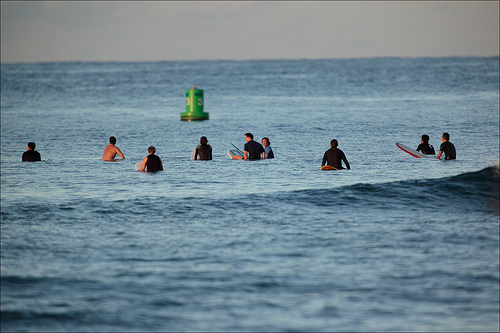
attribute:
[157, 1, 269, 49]
sky — gray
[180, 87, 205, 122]
buoy — floating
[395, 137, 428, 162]
white surfboard —  white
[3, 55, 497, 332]
ocean — blue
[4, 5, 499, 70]
sky —  gray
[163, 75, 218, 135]
buoy —  green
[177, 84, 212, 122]
buoy — green, yellow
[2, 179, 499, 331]
water — blue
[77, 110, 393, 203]
surfers — grouped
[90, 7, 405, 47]
sky — overcast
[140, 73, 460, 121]
horizon — hazy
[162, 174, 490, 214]
wave — mellow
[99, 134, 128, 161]
man —  without  shirt